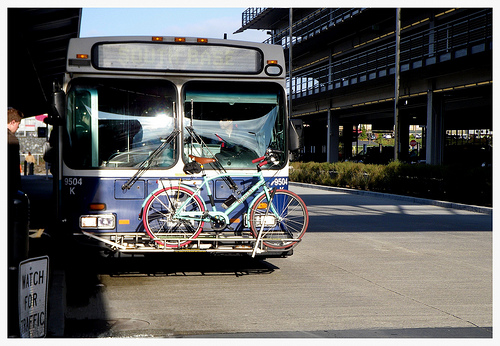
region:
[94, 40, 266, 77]
The bus's destination is displayed here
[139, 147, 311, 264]
The carrier has a bicycle on it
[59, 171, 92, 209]
The bus's ID number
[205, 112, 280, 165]
The bus driver awaits passengers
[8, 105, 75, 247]
This man is preparing to board the bus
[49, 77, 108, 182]
The bus's door is open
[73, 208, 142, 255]
The headlights are on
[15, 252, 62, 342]
A "watch for traffic" sign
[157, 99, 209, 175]
Windshield wipers for when it rains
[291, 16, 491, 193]
A parking garage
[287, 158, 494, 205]
green shrubs growing along the street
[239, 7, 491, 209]
tall concrete multi story building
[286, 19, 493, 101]
metal railings outside a multi story building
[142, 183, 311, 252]
red wheels on a bicycle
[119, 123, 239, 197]
black wipers on a bus windshield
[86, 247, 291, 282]
shadow under the front of a bus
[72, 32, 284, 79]
five orange lights above bus windshield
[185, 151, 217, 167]
brown bicycle seat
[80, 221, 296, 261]
bicycle rack on the front of a bus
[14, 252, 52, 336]
white metal sign next to the bus stop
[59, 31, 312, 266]
bus is parked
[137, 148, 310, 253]
turquoise and red bicycle on the front of a bus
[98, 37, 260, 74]
bus has destination showing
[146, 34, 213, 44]
three orange lights above destination screen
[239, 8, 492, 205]
multi story building next to a bus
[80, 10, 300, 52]
clear blue sky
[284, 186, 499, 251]
building casts a shadow on the ground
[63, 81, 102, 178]
door to the bus is open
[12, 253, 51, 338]
sign advises to watch for traffic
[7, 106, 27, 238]
man waits at the bus stop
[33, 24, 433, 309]
large blue passenger bus with bicycle on front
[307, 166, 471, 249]
shadows on the street next to the bus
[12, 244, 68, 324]
black and white sign: watch for traffic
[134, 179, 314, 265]
bicycle has red wheel detail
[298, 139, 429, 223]
green bushes along the parking garage border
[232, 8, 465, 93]
blue parking garage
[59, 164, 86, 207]
letters are numbers on bus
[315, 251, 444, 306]
street is grey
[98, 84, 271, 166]
light is reflected in the windshield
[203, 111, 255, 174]
man driving bus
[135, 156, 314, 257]
bicycle on the front of a bus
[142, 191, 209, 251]
red bicycle tire on a bike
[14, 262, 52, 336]
white sign with black letters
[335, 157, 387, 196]
shrubs on the side of a street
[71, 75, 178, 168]
window on the front of a bus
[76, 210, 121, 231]
headlight on the front of a bus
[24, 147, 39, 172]
person wearing a yellow shirt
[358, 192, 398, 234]
shadow of a walk way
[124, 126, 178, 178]
windshield wiper on a bus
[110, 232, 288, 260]
bicycle rack on a bus